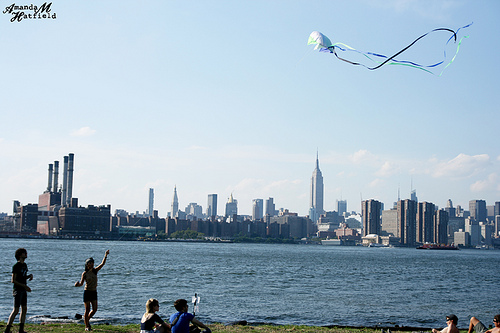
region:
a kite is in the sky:
[274, 12, 481, 77]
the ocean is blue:
[3, 240, 490, 320]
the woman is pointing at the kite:
[61, 245, 145, 326]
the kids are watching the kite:
[140, 279, 226, 331]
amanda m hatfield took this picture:
[3, 3, 70, 28]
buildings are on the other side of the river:
[1, 123, 498, 251]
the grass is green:
[3, 304, 437, 331]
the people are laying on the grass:
[422, 294, 494, 328]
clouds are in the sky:
[251, 136, 478, 199]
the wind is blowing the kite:
[292, 6, 489, 98]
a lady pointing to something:
[86, 257, 103, 313]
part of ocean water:
[326, 257, 341, 277]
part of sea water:
[195, 264, 227, 279]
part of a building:
[365, 212, 380, 217]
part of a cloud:
[223, 113, 244, 125]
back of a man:
[182, 312, 189, 317]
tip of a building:
[311, 155, 323, 160]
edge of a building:
[58, 209, 67, 229]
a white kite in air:
[324, 45, 340, 53]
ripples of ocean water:
[375, 254, 426, 281]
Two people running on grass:
[6, 242, 105, 321]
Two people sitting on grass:
[129, 288, 216, 328]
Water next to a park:
[158, 238, 329, 318]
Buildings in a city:
[24, 153, 389, 248]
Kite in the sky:
[287, 13, 474, 88]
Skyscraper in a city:
[303, 141, 338, 261]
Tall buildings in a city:
[363, 188, 450, 267]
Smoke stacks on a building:
[28, 143, 104, 243]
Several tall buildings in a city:
[136, 178, 367, 255]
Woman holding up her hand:
[61, 245, 141, 327]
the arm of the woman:
[95, 254, 108, 274]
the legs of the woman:
[80, 298, 100, 328]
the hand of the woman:
[103, 244, 114, 257]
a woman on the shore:
[67, 243, 113, 330]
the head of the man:
[9, 244, 32, 267]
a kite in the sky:
[301, 25, 336, 66]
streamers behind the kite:
[331, 14, 481, 79]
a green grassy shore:
[1, 315, 436, 332]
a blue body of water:
[0, 236, 499, 327]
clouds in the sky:
[1, 125, 498, 205]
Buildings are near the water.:
[1, 25, 496, 325]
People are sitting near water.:
[0, 240, 495, 326]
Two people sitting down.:
[130, 286, 211, 328]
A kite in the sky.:
[305, 20, 490, 100]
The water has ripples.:
[230, 255, 440, 305]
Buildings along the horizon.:
[136, 135, 496, 235]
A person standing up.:
[5, 241, 51, 317]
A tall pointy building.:
[290, 131, 336, 226]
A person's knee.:
[462, 311, 482, 323]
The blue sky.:
[67, 30, 255, 115]